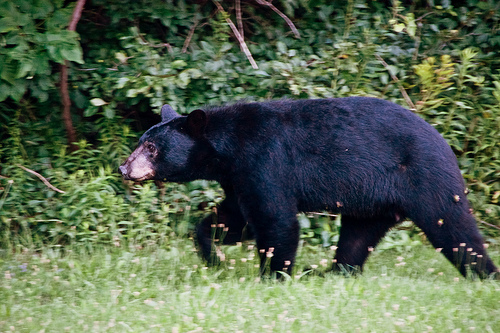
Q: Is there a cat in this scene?
A: No, there are no cats.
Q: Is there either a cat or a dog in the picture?
A: No, there are no cats or dogs.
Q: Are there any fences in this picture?
A: No, there are no fences.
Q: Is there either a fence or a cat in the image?
A: No, there are no fences or cats.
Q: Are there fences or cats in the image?
A: No, there are no fences or cats.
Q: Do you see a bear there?
A: Yes, there is a bear.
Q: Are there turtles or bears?
A: Yes, there is a bear.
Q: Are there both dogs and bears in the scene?
A: No, there is a bear but no dogs.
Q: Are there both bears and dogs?
A: No, there is a bear but no dogs.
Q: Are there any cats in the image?
A: No, there are no cats.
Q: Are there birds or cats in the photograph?
A: No, there are no cats or birds.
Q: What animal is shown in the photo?
A: The animal is a bear.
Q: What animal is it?
A: The animal is a bear.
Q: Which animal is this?
A: This is a bear.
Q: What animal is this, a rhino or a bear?
A: This is a bear.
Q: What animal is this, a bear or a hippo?
A: This is a bear.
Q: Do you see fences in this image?
A: No, there are no fences.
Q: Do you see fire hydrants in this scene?
A: No, there are no fire hydrants.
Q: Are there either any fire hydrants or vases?
A: No, there are no fire hydrants or vases.